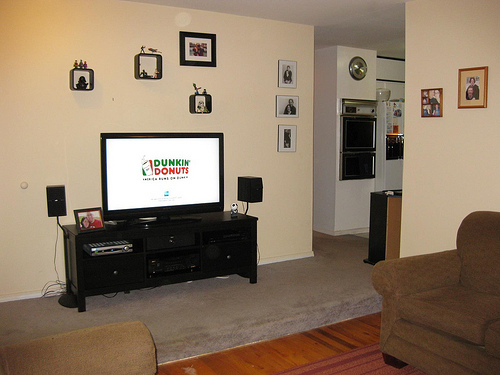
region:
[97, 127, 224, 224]
flat panel television on entertainment stand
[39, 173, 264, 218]
speakers on wall by television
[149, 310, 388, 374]
hardwood floor by chairs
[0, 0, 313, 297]
wall behind television is cream colored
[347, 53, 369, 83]
analog clock hanging above oven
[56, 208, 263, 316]
black entertainment center under TV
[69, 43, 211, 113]
black shelves hang on wall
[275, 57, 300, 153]
white picture frame set on wall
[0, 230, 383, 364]
grey carpet under entertainment center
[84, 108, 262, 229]
this is a tv screen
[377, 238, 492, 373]
this is a sofa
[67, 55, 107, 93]
this is a picture on a wall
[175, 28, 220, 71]
this is a picture on a wall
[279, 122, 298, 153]
this is a picture on a wall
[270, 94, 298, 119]
this is a picture on a wall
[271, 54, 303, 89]
this is a picture on a wall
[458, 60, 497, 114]
this is a picture on a wall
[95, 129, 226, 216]
Large flat screen television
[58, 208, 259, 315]
Dark wood television stand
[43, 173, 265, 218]
Two speakers hanging on a wall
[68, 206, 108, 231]
Framed photograph of two people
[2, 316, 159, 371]
Arm of a brown sofa chair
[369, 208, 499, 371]
End of a brown sofa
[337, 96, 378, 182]
Built in double oven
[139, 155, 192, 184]
Advertisement for Dunkin Donuts on a TV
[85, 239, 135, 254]
Cable box on shelf of a TV stand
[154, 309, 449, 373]
Wood flooring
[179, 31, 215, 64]
a framed picture on the wall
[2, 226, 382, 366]
the floor is carpeted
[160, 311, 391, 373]
hardwood flooring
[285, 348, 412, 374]
red striped area rug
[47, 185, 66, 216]
speaker is mounted on the wall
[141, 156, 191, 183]
advertisement on the TV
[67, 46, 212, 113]
shelves hanging on the wall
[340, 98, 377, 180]
a double oven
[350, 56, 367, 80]
clock above the oven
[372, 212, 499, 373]
a brown couch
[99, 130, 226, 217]
ad for Dunkin' Donuts showing on the screen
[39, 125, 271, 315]
a modest home entertainment center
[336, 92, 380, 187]
double oven at the entrance to the kitchen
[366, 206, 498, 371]
comfortable looking armchair on the right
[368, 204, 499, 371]
this appears to be a recliner chair from the angle of the leg rest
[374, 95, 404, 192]
refrigerator has magnets on the front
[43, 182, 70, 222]
speaker is mounted on the wall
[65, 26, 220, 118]
bric-a-brac and a picture hanging on the wall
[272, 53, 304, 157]
a trio of photographs hanging on the wall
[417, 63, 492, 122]
family photographs hanging on the side wall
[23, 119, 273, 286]
tv on a stand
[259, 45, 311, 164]
a set of pictures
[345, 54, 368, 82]
clock on the wall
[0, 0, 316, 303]
Wall behind flat screen tv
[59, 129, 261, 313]
large flat screen tv on black stand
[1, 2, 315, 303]
ivory painted wall behind black tv stand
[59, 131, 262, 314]
framed picture on tv stand next to flat screen tv on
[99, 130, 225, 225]
flat screen tv is on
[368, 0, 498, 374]
ivory wall behind brown couch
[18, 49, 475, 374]
a scene in the living room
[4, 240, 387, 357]
a gray floor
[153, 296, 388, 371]
a hardwood floor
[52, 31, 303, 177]
frames on the wall